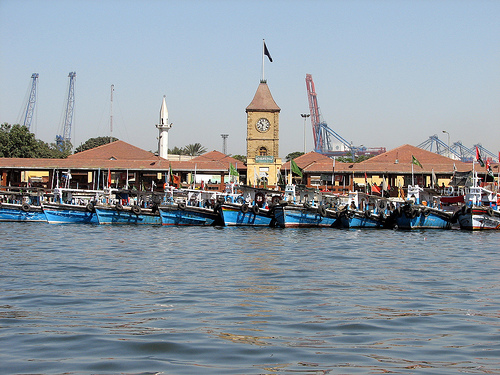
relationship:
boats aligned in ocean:
[1, 177, 498, 234] [1, 222, 498, 375]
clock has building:
[254, 117, 271, 134] [245, 79, 281, 191]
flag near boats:
[409, 156, 421, 183] [2, 188, 499, 227]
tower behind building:
[154, 84, 186, 170] [77, 139, 250, 220]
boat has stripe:
[0, 190, 43, 222] [0, 204, 42, 214]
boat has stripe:
[39, 189, 92, 222] [43, 210, 91, 219]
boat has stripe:
[93, 187, 160, 220] [98, 212, 143, 222]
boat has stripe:
[157, 191, 217, 222] [161, 213, 207, 224]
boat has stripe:
[215, 192, 274, 227] [283, 211, 322, 222]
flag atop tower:
[257, 31, 289, 76] [239, 24, 290, 201]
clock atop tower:
[255, 117, 271, 133] [242, 32, 286, 183]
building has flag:
[245, 79, 281, 191] [260, 34, 272, 88]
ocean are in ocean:
[1, 222, 498, 375] [1, 220, 499, 374]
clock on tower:
[255, 117, 271, 133] [243, 44, 283, 165]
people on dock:
[250, 172, 409, 193] [0, 165, 499, 223]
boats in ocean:
[0, 185, 500, 231] [1, 222, 498, 375]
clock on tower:
[255, 117, 271, 133] [240, 73, 285, 193]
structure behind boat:
[0, 150, 498, 218] [155, 193, 198, 222]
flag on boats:
[316, 178, 390, 194] [6, 143, 498, 253]